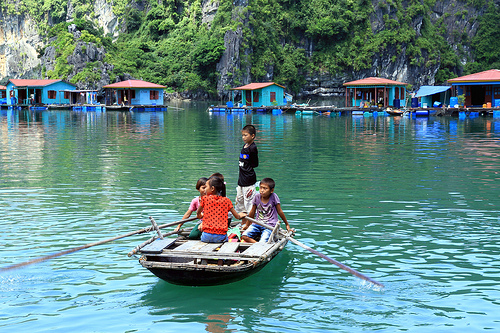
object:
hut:
[230, 80, 286, 107]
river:
[1, 97, 499, 332]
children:
[192, 170, 246, 243]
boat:
[128, 219, 297, 288]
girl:
[195, 172, 249, 246]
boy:
[235, 124, 261, 227]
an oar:
[245, 216, 385, 289]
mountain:
[1, 0, 500, 98]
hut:
[5, 77, 78, 107]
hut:
[342, 76, 409, 109]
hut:
[414, 84, 453, 115]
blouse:
[198, 194, 234, 235]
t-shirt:
[238, 141, 259, 187]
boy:
[240, 178, 291, 244]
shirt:
[250, 192, 279, 228]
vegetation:
[0, 1, 500, 103]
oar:
[1, 216, 200, 271]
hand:
[238, 211, 248, 218]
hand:
[197, 212, 203, 220]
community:
[0, 69, 499, 118]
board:
[140, 237, 176, 253]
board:
[171, 239, 210, 253]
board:
[196, 242, 224, 253]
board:
[217, 242, 239, 253]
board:
[241, 241, 275, 256]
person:
[28, 91, 35, 108]